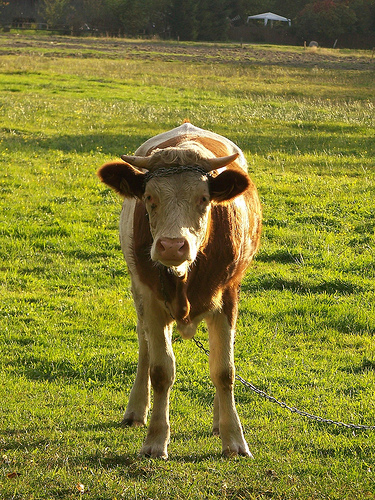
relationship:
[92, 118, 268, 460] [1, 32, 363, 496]
cow standing on grass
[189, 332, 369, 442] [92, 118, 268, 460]
chain hanging from cow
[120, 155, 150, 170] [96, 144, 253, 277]
horn are on head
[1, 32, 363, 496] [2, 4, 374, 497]
grass on area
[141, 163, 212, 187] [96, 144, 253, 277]
chain wrapped on head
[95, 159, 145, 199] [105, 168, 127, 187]
ear has fur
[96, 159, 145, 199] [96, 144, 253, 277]
ear on head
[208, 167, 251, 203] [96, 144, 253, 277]
ear on head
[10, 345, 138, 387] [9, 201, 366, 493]
shadow on grass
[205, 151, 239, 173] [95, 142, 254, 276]
horn are on steer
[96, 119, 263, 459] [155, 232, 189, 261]
cow has nose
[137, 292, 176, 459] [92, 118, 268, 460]
front leg belonging to cow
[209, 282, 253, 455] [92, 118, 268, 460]
front leg belonging to cow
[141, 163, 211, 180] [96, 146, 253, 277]
chain wrapped around head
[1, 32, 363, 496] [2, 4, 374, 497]
grass covering area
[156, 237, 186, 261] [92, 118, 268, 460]
nose belonging to cow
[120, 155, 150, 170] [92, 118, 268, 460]
horn belonging to cow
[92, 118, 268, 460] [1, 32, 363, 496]
cow standing in grass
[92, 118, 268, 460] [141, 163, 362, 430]
cow attached to chain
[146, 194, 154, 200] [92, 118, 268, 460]
eye belonging to cow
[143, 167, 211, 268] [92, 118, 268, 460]
face belonging to cow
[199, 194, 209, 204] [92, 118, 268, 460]
eye belonging to cow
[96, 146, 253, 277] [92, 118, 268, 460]
head belonging to cow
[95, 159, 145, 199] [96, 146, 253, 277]
ear attached to head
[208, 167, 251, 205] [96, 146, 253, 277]
ear attached to head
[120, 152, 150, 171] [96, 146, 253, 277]
horn attached to head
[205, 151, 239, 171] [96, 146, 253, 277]
horn attached to head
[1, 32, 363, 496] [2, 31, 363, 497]
grass covering area